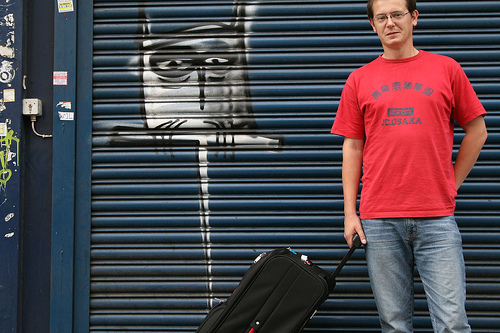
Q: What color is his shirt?
A: Red.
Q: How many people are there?
A: One.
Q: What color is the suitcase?
A: Black.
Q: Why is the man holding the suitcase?
A: It belongs to him.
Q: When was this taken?
A: Daytime.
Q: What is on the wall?
A: Owl graffiti.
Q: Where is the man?
A: In front of the graffiti.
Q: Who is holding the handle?
A: The man.